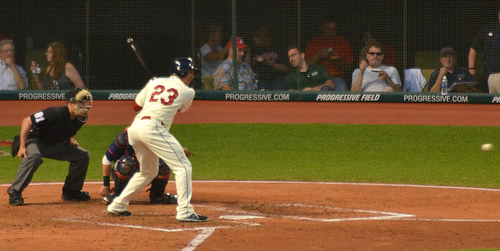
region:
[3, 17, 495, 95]
spectators sitting in stands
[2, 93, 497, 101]
white words on green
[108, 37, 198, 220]
player with bat at homeplate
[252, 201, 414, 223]
lines indicating batter's box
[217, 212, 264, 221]
white surface of plate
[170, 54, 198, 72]
shine on batter's helmet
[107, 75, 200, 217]
white uniform on player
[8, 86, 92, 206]
umpire in crouched position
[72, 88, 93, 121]
mask on umpires face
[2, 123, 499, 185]
green grass on field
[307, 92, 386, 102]
name of baseball field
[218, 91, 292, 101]
adverstiing for baseball field sponsor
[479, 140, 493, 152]
baseball moving toward batter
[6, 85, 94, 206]
umpire in squatted position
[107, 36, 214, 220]
batter looking at baseball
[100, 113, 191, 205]
catcher waiting on baseball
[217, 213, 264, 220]
home plate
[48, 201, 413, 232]
chalk outline of batter's box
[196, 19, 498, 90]
spectators at a baseball game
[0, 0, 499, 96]
protective fence around basebal field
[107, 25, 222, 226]
man wearing a helmet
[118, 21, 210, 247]
man wearing a white shirt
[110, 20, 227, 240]
man wearing white pants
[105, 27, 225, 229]
man wearing tennis shoes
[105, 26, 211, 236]
man holding a bat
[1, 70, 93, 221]
man wearing face guard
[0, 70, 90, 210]
man wearing black shirt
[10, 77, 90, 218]
man wearing gray pants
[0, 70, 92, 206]
man wearing black shoes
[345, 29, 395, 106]
man wearing sun shades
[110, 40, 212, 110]
a man holding a bat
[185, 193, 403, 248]
white chalk lines on a base ball field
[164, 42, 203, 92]
a man wearing a helmet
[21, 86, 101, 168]
a man bent down with his hand on his knees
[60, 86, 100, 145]
a man wearing a safety mask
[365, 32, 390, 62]
a man wearing sunglasses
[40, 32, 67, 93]
a woman with long hair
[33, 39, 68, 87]
a woman with red hair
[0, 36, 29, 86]
a man touching his face with his hand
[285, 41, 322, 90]
a man wearing a green shirt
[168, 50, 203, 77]
Helmet on man's head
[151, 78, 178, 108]
Red number on man's back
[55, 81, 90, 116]
Mask on man's face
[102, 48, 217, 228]
Man wearing a white uniform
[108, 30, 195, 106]
Bat in man's hand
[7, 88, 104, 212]
Man wearing a black uniform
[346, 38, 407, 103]
Man wearing a white shirt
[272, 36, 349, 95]
Man wearing a green shirt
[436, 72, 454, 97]
Water bottle behind fence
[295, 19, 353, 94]
Man wearing a orange shirt